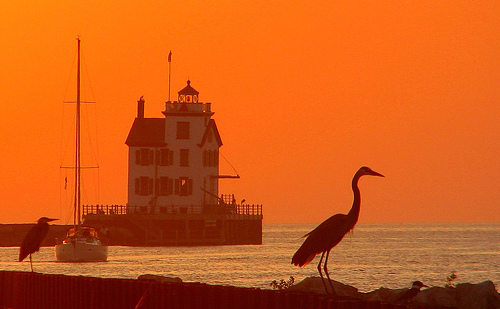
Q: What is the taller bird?
A: A crane.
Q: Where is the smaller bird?
A: End of ledge.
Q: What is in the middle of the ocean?
A: Lighthouse.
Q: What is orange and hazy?
A: Sky.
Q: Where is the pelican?
A: On seashore.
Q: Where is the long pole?
A: Attached to boat.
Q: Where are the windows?
A: On the lighthouse.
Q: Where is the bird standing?
A: On the fence.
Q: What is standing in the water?
A: A lighthouse.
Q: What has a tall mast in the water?
A: The boat.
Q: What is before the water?
A: A fence.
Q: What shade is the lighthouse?
A: White with black trim.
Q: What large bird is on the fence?
A: A pelican.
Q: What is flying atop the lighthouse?
A: A flag.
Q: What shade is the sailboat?
A: White.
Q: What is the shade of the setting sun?
A: Orange.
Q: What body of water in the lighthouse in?
A: The ocean.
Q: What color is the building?
A: White.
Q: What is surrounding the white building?
A: Fence.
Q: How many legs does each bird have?
A: 2.